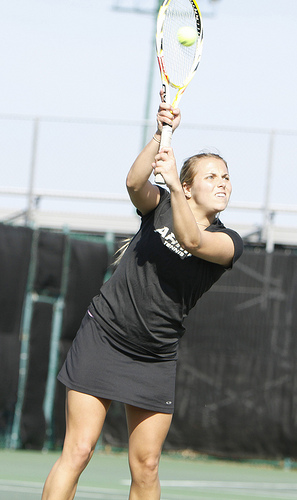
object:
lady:
[40, 91, 244, 499]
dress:
[55, 302, 181, 416]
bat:
[153, 0, 206, 183]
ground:
[1, 448, 296, 499]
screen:
[0, 234, 297, 453]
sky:
[0, 0, 297, 243]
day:
[0, 0, 297, 499]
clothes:
[56, 185, 241, 416]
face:
[191, 158, 232, 213]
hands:
[151, 145, 178, 188]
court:
[0, 232, 297, 499]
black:
[55, 186, 242, 415]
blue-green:
[8, 227, 73, 440]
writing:
[165, 400, 172, 405]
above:
[0, 0, 296, 136]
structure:
[3, 236, 297, 452]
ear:
[182, 180, 192, 198]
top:
[89, 184, 243, 365]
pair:
[42, 385, 171, 499]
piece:
[152, 134, 162, 144]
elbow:
[124, 167, 142, 195]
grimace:
[196, 159, 232, 210]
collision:
[174, 21, 200, 50]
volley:
[124, 0, 245, 267]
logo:
[154, 226, 191, 259]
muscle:
[173, 211, 186, 244]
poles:
[26, 230, 40, 291]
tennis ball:
[176, 25, 198, 49]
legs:
[36, 392, 111, 498]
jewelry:
[153, 135, 161, 143]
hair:
[179, 152, 229, 190]